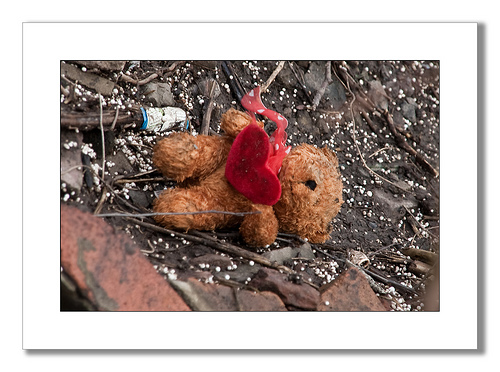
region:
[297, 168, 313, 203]
Bear has black nose.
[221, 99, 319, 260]
Bear has heart on tummy.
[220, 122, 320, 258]
Heart on bear is large.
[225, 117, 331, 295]
Heart on bear is red.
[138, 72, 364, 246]
Brown stuffed animal on ground.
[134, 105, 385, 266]
Brown stuffed animal is a teddy bear.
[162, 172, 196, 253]
Bear has brown legs.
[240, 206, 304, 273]
Bear has brown arm.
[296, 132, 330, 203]
Bear has brown face.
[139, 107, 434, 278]
Bear is laying in the mud.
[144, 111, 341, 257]
a little brown teddy bear sitting on the ground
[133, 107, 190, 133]
an empty can next to the bear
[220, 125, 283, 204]
the red heart the bear is holding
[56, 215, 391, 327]
some red bricks laying around next to the bear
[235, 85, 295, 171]
a red ribbon attached to the bear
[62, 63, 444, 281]
the ground that everything is laying on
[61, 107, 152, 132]
a piece of wood laying on the ground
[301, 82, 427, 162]
assorted trash on the ground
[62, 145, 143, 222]
some more of the trash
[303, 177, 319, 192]
the nose of the teddy bear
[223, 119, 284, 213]
red heart on bear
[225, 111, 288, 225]
heart on top of teddy bear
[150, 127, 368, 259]
teddy bear lying on ground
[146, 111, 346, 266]
little bear on the ground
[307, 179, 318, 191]
teddy bear's black nose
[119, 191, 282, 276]
stick under little bear's right leg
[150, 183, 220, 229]
teddy bears left leg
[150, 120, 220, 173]
teddy bears right leg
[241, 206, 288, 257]
teddy bears left arm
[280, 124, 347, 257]
teddy bears head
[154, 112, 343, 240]
Small brown stuffed bear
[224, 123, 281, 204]
Red heart on bear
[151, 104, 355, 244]
Stuffed bear on ground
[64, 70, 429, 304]
Dirty and rocky ground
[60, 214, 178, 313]
Brown piece of rock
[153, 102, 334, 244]
Old brown stuffed bear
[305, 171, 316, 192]
Black nose on bear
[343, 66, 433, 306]
White pieces on ground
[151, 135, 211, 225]
Legs of stuffed bear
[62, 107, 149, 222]
Dead branches on ground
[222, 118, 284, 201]
Dirty red toy heart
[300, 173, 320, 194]
Black button bear nose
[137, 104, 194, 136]
Bit of blue trash near the bear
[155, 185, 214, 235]
Left leg of toy bear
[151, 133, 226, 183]
Right leg of toy bear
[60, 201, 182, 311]
Red colored brick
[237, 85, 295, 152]
Red ribbon with white hearts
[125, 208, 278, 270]
Brown and dirty twig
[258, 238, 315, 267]
Grey colored rock in ground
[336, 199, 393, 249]
Patch of black dirt